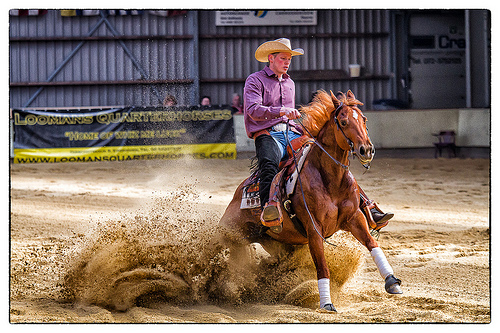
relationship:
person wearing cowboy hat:
[243, 51, 394, 236] [254, 38, 305, 63]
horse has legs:
[213, 89, 405, 315] [305, 214, 406, 313]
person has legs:
[243, 51, 394, 236] [256, 129, 396, 235]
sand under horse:
[10, 152, 491, 322] [213, 89, 405, 315]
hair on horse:
[297, 88, 339, 138] [213, 89, 405, 315]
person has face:
[243, 51, 394, 236] [275, 51, 293, 73]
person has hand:
[243, 51, 394, 236] [282, 106, 302, 122]